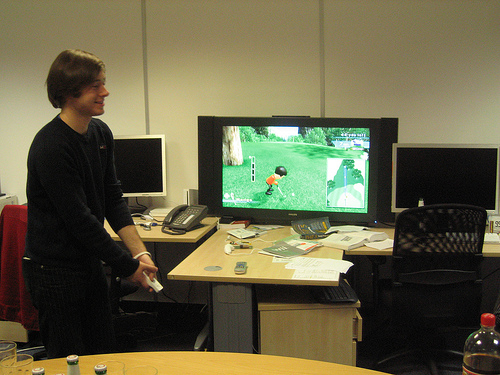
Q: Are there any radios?
A: No, there are no radios.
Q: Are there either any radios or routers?
A: No, there are no radios or routers.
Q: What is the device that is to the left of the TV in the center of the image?
A: The device is a computer monitor.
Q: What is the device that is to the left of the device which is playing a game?
A: The device is a computer monitor.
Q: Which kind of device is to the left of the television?
A: The device is a computer monitor.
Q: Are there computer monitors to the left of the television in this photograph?
A: Yes, there is a computer monitor to the left of the television.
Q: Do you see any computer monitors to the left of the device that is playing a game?
A: Yes, there is a computer monitor to the left of the television.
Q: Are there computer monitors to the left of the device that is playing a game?
A: Yes, there is a computer monitor to the left of the television.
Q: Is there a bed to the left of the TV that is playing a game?
A: No, there is a computer monitor to the left of the television.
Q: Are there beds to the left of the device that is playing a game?
A: No, there is a computer monitor to the left of the television.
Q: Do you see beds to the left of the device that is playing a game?
A: No, there is a computer monitor to the left of the television.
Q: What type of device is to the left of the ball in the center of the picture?
A: The device is a computer monitor.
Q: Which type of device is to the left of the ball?
A: The device is a computer monitor.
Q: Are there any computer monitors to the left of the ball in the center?
A: Yes, there is a computer monitor to the left of the ball.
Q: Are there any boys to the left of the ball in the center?
A: No, there is a computer monitor to the left of the ball.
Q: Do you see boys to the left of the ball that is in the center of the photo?
A: No, there is a computer monitor to the left of the ball.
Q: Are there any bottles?
A: Yes, there is a bottle.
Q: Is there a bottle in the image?
A: Yes, there is a bottle.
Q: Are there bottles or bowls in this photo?
A: Yes, there is a bottle.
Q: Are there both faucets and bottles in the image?
A: No, there is a bottle but no faucets.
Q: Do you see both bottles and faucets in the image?
A: No, there is a bottle but no faucets.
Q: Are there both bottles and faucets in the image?
A: No, there is a bottle but no faucets.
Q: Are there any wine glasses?
A: No, there are no wine glasses.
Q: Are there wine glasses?
A: No, there are no wine glasses.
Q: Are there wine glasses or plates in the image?
A: No, there are no wine glasses or plates.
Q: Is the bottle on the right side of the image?
A: Yes, the bottle is on the right of the image.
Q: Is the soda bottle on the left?
A: No, the bottle is on the right of the image.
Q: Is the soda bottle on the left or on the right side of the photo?
A: The bottle is on the right of the image.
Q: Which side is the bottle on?
A: The bottle is on the right of the image.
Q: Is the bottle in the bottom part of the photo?
A: Yes, the bottle is in the bottom of the image.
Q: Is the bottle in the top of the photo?
A: No, the bottle is in the bottom of the image.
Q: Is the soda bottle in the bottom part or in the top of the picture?
A: The bottle is in the bottom of the image.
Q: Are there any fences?
A: No, there are no fences.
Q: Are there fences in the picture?
A: No, there are no fences.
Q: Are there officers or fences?
A: No, there are no fences or officers.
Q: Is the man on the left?
A: Yes, the man is on the left of the image.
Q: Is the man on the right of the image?
A: No, the man is on the left of the image.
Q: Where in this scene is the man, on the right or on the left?
A: The man is on the left of the image.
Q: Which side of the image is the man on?
A: The man is on the left of the image.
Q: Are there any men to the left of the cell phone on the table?
A: Yes, there is a man to the left of the cellphone.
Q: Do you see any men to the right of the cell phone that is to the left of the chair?
A: No, the man is to the left of the mobile phone.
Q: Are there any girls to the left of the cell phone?
A: No, there is a man to the left of the cell phone.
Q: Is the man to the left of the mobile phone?
A: Yes, the man is to the left of the mobile phone.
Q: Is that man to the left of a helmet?
A: No, the man is to the left of the mobile phone.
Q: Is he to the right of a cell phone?
A: No, the man is to the left of a cell phone.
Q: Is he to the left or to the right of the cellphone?
A: The man is to the left of the cellphone.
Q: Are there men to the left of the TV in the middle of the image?
A: Yes, there is a man to the left of the television.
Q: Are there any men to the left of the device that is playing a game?
A: Yes, there is a man to the left of the television.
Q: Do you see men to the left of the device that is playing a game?
A: Yes, there is a man to the left of the television.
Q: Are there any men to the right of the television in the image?
A: No, the man is to the left of the television.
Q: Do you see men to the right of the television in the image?
A: No, the man is to the left of the television.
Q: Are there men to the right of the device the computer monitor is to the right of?
A: No, the man is to the left of the television.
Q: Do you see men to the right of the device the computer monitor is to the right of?
A: No, the man is to the left of the television.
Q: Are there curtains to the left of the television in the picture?
A: No, there is a man to the left of the television.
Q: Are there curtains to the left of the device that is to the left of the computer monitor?
A: No, there is a man to the left of the television.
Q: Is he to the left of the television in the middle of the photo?
A: Yes, the man is to the left of the television.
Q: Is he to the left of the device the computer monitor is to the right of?
A: Yes, the man is to the left of the television.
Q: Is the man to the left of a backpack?
A: No, the man is to the left of the television.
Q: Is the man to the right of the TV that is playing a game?
A: No, the man is to the left of the TV.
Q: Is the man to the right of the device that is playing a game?
A: No, the man is to the left of the TV.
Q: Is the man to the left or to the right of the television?
A: The man is to the left of the television.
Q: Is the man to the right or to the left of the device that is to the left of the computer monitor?
A: The man is to the left of the television.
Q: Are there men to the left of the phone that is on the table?
A: Yes, there is a man to the left of the telephone.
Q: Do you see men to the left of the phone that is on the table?
A: Yes, there is a man to the left of the telephone.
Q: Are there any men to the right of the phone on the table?
A: No, the man is to the left of the phone.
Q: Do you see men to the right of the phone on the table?
A: No, the man is to the left of the phone.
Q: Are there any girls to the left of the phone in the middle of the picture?
A: No, there is a man to the left of the telephone.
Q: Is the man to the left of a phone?
A: Yes, the man is to the left of a phone.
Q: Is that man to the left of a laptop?
A: No, the man is to the left of a phone.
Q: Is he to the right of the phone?
A: No, the man is to the left of the phone.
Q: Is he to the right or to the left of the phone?
A: The man is to the left of the phone.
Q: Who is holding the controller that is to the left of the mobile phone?
A: The man is holding the controller.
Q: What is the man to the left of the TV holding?
A: The man is holding the controller.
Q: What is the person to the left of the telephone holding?
A: The man is holding the controller.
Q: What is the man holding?
A: The man is holding the controller.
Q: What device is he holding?
A: The man is holding the controller.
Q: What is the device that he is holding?
A: The device is a controller.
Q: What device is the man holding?
A: The man is holding the controller.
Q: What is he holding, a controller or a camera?
A: The man is holding a controller.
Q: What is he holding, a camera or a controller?
A: The man is holding a controller.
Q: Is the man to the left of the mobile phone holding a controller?
A: Yes, the man is holding a controller.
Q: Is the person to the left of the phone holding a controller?
A: Yes, the man is holding a controller.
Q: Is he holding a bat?
A: No, the man is holding a controller.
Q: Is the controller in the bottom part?
A: Yes, the controller is in the bottom of the image.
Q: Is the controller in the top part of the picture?
A: No, the controller is in the bottom of the image.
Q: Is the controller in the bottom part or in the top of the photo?
A: The controller is in the bottom of the image.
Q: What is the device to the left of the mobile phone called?
A: The device is a controller.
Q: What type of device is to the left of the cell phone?
A: The device is a controller.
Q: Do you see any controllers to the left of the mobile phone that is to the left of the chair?
A: Yes, there is a controller to the left of the cell phone.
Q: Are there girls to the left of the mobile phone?
A: No, there is a controller to the left of the mobile phone.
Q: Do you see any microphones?
A: No, there are no microphones.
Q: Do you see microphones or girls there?
A: No, there are no microphones or girls.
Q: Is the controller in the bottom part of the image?
A: Yes, the controller is in the bottom of the image.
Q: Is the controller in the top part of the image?
A: No, the controller is in the bottom of the image.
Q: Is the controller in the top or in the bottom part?
A: The controller is in the bottom of the image.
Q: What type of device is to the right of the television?
A: The device is a computer monitor.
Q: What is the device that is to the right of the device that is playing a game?
A: The device is a computer monitor.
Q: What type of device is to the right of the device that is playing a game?
A: The device is a computer monitor.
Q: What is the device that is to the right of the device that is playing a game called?
A: The device is a computer monitor.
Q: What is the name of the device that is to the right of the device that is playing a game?
A: The device is a computer monitor.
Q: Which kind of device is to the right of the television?
A: The device is a computer monitor.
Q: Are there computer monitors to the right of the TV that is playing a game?
A: Yes, there is a computer monitor to the right of the TV.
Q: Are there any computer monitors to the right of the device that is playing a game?
A: Yes, there is a computer monitor to the right of the TV.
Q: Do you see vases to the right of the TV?
A: No, there is a computer monitor to the right of the TV.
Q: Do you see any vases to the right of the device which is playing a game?
A: No, there is a computer monitor to the right of the TV.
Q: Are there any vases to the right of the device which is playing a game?
A: No, there is a computer monitor to the right of the TV.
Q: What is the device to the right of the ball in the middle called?
A: The device is a computer monitor.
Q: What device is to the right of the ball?
A: The device is a computer monitor.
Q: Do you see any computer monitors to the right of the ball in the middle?
A: Yes, there is a computer monitor to the right of the ball.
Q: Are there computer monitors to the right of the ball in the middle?
A: Yes, there is a computer monitor to the right of the ball.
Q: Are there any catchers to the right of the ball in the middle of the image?
A: No, there is a computer monitor to the right of the ball.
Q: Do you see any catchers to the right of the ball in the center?
A: No, there is a computer monitor to the right of the ball.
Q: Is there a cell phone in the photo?
A: Yes, there is a cell phone.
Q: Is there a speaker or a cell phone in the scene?
A: Yes, there is a cell phone.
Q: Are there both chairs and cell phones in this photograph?
A: Yes, there are both a cell phone and a chair.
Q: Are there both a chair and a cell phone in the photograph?
A: Yes, there are both a cell phone and a chair.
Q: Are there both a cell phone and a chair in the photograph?
A: Yes, there are both a cell phone and a chair.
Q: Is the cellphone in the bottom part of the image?
A: Yes, the cellphone is in the bottom of the image.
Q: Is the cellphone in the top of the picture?
A: No, the cellphone is in the bottom of the image.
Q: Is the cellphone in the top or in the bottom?
A: The cellphone is in the bottom of the image.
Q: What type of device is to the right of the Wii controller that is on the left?
A: The device is a cell phone.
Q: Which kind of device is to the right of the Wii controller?
A: The device is a cell phone.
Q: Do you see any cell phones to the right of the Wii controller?
A: Yes, there is a cell phone to the right of the Wii controller.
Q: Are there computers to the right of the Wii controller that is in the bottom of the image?
A: No, there is a cell phone to the right of the Wii controller.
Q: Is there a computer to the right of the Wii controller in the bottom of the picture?
A: No, there is a cell phone to the right of the Wii controller.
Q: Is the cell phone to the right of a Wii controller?
A: Yes, the cell phone is to the right of a Wii controller.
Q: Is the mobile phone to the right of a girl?
A: No, the mobile phone is to the right of a Wii controller.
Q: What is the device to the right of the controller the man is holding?
A: The device is a cell phone.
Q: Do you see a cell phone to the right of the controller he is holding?
A: Yes, there is a cell phone to the right of the controller.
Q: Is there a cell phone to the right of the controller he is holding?
A: Yes, there is a cell phone to the right of the controller.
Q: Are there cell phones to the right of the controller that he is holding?
A: Yes, there is a cell phone to the right of the controller.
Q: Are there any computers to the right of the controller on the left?
A: No, there is a cell phone to the right of the controller.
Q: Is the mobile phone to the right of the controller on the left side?
A: Yes, the mobile phone is to the right of the controller.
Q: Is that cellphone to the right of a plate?
A: No, the cellphone is to the right of the controller.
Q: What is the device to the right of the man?
A: The device is a cell phone.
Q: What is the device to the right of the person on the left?
A: The device is a cell phone.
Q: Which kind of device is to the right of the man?
A: The device is a cell phone.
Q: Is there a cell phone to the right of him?
A: Yes, there is a cell phone to the right of the man.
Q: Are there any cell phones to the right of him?
A: Yes, there is a cell phone to the right of the man.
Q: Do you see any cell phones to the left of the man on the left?
A: No, the cell phone is to the right of the man.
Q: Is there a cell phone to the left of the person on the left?
A: No, the cell phone is to the right of the man.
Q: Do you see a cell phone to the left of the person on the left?
A: No, the cell phone is to the right of the man.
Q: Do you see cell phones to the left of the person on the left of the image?
A: No, the cell phone is to the right of the man.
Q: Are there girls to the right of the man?
A: No, there is a cell phone to the right of the man.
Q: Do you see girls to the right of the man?
A: No, there is a cell phone to the right of the man.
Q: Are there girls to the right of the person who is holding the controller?
A: No, there is a cell phone to the right of the man.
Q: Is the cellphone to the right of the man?
A: Yes, the cellphone is to the right of the man.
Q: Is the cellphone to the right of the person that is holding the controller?
A: Yes, the cellphone is to the right of the man.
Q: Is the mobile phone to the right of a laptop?
A: No, the mobile phone is to the right of the man.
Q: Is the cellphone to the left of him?
A: No, the cellphone is to the right of a man.